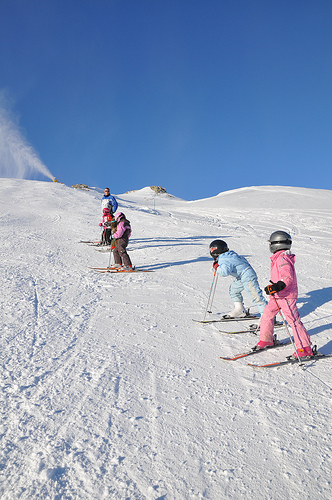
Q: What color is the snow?
A: White.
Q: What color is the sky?
A: Blue.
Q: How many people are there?
A: Five.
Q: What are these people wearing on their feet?
A: Skis.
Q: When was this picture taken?
A: During the day.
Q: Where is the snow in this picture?
A: On the ground.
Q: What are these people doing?
A: Sking.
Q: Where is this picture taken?
A: On a mountain.